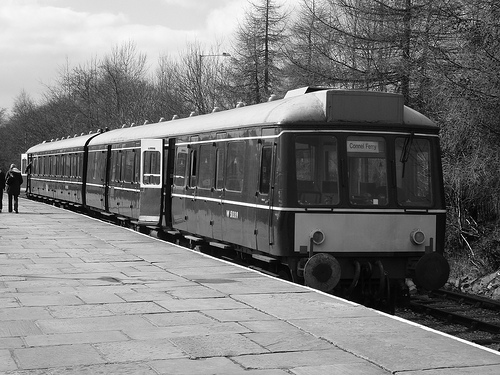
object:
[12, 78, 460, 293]
train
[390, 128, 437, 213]
windows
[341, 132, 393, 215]
windows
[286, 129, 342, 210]
windows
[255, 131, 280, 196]
windows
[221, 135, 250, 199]
windows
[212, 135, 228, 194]
windows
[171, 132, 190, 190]
windows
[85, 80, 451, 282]
cars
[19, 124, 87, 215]
cars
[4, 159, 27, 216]
person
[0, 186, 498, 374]
sidewalk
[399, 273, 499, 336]
track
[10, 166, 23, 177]
hat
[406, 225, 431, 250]
headlight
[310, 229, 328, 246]
headlight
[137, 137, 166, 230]
door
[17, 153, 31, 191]
door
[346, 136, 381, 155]
sign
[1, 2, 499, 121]
sky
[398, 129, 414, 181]
wiper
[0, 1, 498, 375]
photograph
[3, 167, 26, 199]
coat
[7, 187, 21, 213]
pants